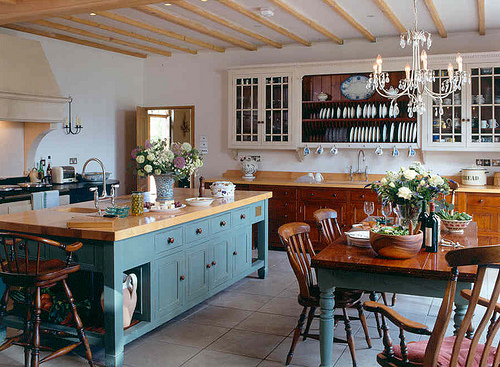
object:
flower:
[173, 155, 189, 171]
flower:
[170, 141, 184, 157]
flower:
[143, 139, 156, 148]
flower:
[129, 145, 142, 158]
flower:
[180, 141, 192, 154]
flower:
[154, 168, 163, 175]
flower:
[145, 152, 159, 163]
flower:
[134, 153, 146, 165]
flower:
[141, 162, 156, 176]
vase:
[149, 169, 178, 203]